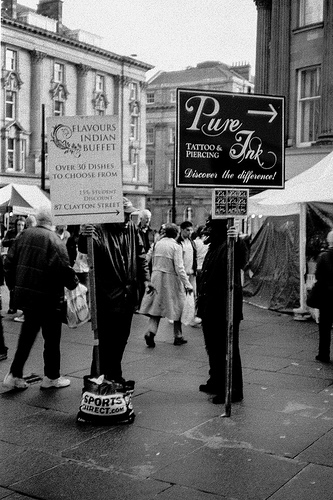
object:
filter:
[15, 27, 331, 413]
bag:
[73, 375, 137, 430]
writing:
[80, 390, 125, 407]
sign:
[172, 86, 287, 195]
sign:
[45, 113, 122, 229]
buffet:
[262, 225, 328, 316]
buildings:
[0, 0, 155, 235]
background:
[0, 0, 332, 499]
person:
[139, 222, 204, 349]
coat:
[137, 236, 195, 324]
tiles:
[59, 420, 210, 482]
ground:
[0, 297, 332, 499]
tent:
[247, 148, 331, 321]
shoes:
[209, 381, 245, 406]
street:
[0, 288, 328, 500]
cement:
[59, 419, 208, 481]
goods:
[217, 214, 307, 280]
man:
[192, 196, 251, 410]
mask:
[174, 223, 237, 263]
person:
[75, 193, 150, 388]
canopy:
[245, 149, 333, 220]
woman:
[2, 207, 80, 392]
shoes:
[38, 372, 72, 392]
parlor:
[290, 296, 329, 398]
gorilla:
[193, 213, 250, 406]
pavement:
[0, 291, 332, 499]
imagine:
[182, 165, 219, 183]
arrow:
[243, 97, 278, 129]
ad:
[94, 391, 206, 448]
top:
[29, 10, 148, 77]